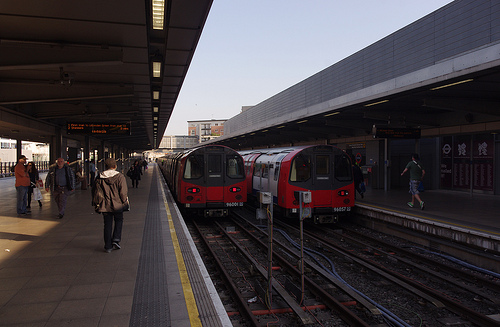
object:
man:
[401, 152, 425, 211]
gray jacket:
[92, 171, 130, 214]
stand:
[299, 192, 311, 306]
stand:
[259, 190, 272, 311]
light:
[152, 2, 166, 29]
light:
[153, 62, 161, 77]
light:
[430, 80, 470, 91]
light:
[363, 99, 389, 106]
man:
[91, 158, 131, 253]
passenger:
[130, 161, 143, 188]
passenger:
[352, 164, 366, 200]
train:
[236, 141, 354, 224]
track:
[192, 223, 372, 326]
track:
[401, 276, 499, 326]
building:
[159, 119, 227, 148]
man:
[12, 152, 30, 217]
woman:
[26, 163, 43, 208]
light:
[229, 187, 241, 192]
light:
[187, 187, 200, 193]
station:
[0, 0, 500, 327]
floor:
[22, 252, 128, 324]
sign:
[66, 118, 131, 135]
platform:
[0, 162, 234, 327]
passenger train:
[157, 145, 247, 218]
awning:
[0, 0, 215, 149]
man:
[44, 158, 75, 219]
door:
[204, 152, 228, 203]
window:
[316, 156, 327, 175]